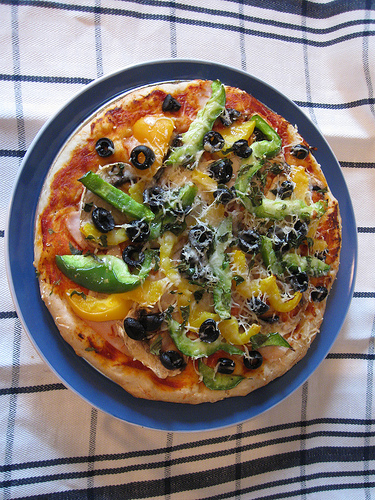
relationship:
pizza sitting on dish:
[30, 76, 344, 408] [4, 57, 357, 434]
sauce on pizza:
[35, 83, 342, 390] [27, 65, 363, 416]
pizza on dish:
[30, 76, 344, 408] [4, 57, 357, 434]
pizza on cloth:
[30, 76, 344, 408] [2, 1, 373, 499]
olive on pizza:
[213, 158, 236, 181] [30, 76, 344, 408]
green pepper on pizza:
[46, 247, 159, 298] [30, 76, 344, 408]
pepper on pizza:
[130, 110, 178, 181] [30, 76, 344, 408]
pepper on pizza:
[231, 249, 303, 311] [30, 76, 344, 408]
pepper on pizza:
[54, 250, 159, 293] [30, 76, 344, 408]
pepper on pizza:
[77, 170, 156, 222] [30, 76, 344, 408]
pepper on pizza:
[166, 76, 227, 171] [30, 76, 344, 408]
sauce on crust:
[37, 78, 341, 391] [111, 363, 149, 400]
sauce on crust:
[37, 78, 341, 391] [40, 293, 74, 326]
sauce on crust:
[37, 78, 341, 391] [263, 347, 292, 375]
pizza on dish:
[33, 78, 343, 405] [234, 49, 316, 120]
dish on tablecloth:
[6, 60, 372, 437] [1, 2, 373, 497]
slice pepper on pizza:
[93, 96, 338, 283] [30, 76, 344, 408]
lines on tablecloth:
[291, 5, 327, 18] [1, 2, 373, 497]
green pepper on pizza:
[76, 172, 154, 221] [30, 76, 344, 408]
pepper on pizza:
[123, 113, 177, 181] [30, 76, 344, 408]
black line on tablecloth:
[0, 413, 373, 499] [1, 2, 373, 497]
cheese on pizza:
[54, 156, 302, 324] [63, 123, 343, 373]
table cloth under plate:
[116, 434, 293, 492] [95, 389, 309, 454]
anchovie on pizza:
[132, 145, 145, 168] [30, 76, 344, 408]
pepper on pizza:
[55, 250, 153, 294] [30, 76, 344, 408]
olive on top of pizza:
[211, 355, 238, 374] [10, 79, 363, 394]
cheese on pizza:
[149, 175, 211, 230] [25, 93, 366, 406]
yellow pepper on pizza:
[262, 275, 302, 312] [30, 76, 344, 408]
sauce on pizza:
[37, 78, 341, 391] [14, 49, 362, 440]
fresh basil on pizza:
[67, 241, 86, 255] [30, 76, 344, 408]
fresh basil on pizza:
[68, 288, 85, 297] [30, 76, 344, 408]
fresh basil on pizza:
[52, 279, 62, 285] [30, 76, 344, 408]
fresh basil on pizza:
[47, 226, 52, 235] [30, 76, 344, 408]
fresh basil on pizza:
[85, 232, 94, 241] [30, 76, 344, 408]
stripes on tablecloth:
[2, 5, 367, 496] [1, 2, 373, 497]